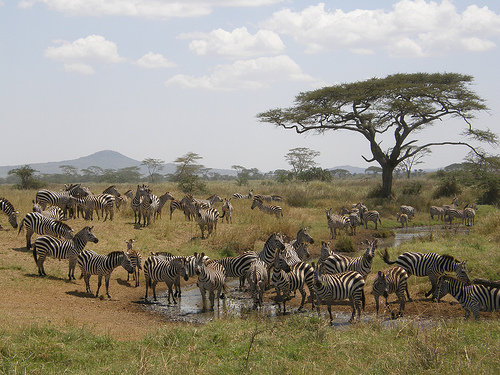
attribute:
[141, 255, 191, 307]
zebra — eating, numerous, wild, drinking, striped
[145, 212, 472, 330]
river — small, muddy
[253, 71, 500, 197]
tree — large, tall, green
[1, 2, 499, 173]
sky — blue, cloudy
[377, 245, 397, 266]
tail — swinging, wagging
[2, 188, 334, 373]
plain — grassy, green